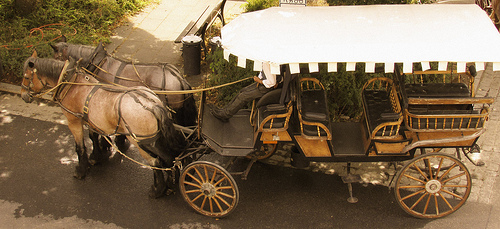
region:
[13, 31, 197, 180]
Team of horses drawing the wagon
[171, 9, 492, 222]
Horse drawn wagon/buggy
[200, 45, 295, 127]
Driver of the buggy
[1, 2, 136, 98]
Foliage to the left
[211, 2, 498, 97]
White canopy over the buggy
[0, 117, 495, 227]
Road that the horse and buggy are on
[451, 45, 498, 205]
Stone walkway to the right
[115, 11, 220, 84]
Wooden walkway behind the horses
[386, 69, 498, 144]
Backseat of the horse drawn buggy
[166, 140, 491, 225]
Left wheels of the buggy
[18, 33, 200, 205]
Two horses pulling a cart.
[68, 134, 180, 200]
Horse with black legs.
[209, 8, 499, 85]
White roof of carriage.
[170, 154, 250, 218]
Front wooden carriage wheel.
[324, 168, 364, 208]
Carriage steps.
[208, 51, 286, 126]
Bottom half of carriage driver.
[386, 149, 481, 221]
Back wooden carriage wheel.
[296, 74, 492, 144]
black seats inside of carriage.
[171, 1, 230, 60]
Wooden bench.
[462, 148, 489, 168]
Back foot stool on carriage.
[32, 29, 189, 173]
horses in front of carriage are tan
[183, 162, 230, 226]
car has brown wheels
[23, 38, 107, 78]
horses have brown manes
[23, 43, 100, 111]
horses have brown bridles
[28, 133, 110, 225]
road is dark grey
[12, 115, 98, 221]
road near horses is wet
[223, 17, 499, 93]
carriage has white roof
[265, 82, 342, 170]
brown seats on carriage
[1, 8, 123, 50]
green grass next to horses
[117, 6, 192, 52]
white road behind horses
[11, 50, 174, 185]
this is a horse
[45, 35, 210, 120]
this is a horse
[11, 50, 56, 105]
this is a head of a horse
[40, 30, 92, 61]
this is a head of a horse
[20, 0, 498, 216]
this is a horse pulled cart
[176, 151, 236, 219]
this is a wheel of the cart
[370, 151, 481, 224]
this is a wheel of the cart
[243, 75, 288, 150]
these are chairs of the cart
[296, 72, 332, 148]
these are chairs of the cart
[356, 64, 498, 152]
these are chairs of the cart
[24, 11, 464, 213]
TWO HORSES PULLING CARRIAGE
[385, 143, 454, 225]
ROUND WOODEN CARRIAGE TIRE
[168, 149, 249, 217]
ROUND WOODEN CARRIAGE TIRE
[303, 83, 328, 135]
BLACK CUSHION ON SEAT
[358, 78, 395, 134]
BLACK CUSHION ON SEAT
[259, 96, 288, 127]
BLACK CUSHION ON SEAT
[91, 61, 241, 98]
ROPE PULLING CARRIAGE FROM HORSES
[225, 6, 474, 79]
WHITE ROOF OF CARRIAGE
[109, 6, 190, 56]
SIDEWALK TO THE RIGHT OF HORSES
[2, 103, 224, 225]
WET SPOTS ON PAVED ROAD